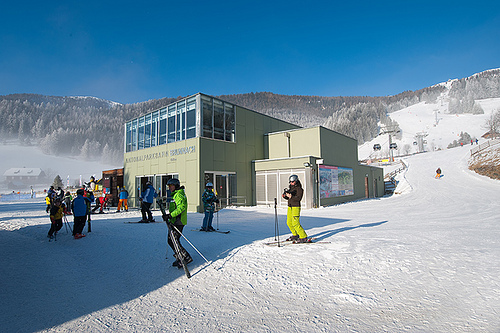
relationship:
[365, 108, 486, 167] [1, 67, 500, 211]
ski lift on top of mountain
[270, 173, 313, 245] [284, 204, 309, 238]
woman wearing ski pants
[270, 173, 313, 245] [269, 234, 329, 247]
woman ready to ski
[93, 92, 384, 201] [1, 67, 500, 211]
ski lodge on top of mountain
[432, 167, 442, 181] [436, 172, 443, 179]
people wearing bright orange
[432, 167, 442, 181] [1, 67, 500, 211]
people coming down mountain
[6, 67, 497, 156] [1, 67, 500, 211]
trees on side of mountain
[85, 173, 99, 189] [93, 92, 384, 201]
blow up penguin next to ski lodge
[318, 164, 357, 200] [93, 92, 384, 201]
map on side of ski lodge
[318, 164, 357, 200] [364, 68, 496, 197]
map for ski hills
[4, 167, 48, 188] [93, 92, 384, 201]
building behind ski lodge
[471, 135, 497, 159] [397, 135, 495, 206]
safety fence along ski trail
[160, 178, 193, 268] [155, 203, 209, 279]
people getting ready to ski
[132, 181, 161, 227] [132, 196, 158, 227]
people getting ready to ski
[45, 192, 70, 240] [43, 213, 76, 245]
people getting ready to ski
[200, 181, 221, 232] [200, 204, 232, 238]
people getting ready to ski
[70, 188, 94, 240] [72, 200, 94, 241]
people getting ready to ski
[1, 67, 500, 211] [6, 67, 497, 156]
mountain covered in trees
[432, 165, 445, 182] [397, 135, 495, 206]
people coming down ski slope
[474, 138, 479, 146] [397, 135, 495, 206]
people coming down ski slope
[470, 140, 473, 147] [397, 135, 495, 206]
people coming down ski slope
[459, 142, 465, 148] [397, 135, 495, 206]
people coming down ski slope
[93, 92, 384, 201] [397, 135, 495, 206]
ski lodge at base of ski slope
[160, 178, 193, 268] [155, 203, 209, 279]
people carrying skis and ski poles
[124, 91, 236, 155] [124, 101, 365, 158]
windows on second floor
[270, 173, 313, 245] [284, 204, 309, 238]
person wearing ski pants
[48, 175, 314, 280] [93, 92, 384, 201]
people near ski lodge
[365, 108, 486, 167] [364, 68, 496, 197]
ski lift in background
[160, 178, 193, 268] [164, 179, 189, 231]
people wearing a jacket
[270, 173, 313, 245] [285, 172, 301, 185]
woman wearing helmet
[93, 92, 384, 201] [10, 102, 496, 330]
ski lodge on top of snow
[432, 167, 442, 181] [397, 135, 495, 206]
people on top of hill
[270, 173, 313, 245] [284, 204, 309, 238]
woman wearing yellow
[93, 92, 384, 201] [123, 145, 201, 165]
ski lodge has writing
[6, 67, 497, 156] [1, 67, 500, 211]
trees on top of mountain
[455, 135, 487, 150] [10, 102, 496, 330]
three people in snow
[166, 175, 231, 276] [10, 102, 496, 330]
two people in snow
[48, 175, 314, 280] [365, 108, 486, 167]
people use ski lift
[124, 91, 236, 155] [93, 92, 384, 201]
windows on side of ski lodge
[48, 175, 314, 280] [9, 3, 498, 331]
skiers in photo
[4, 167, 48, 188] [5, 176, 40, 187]
building made of logs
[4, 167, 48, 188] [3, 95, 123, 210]
building in background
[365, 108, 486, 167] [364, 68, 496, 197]
ski lift on top of slope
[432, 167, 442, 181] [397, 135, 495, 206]
people coming down ski slope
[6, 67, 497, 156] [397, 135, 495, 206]
trees along sides of ski trail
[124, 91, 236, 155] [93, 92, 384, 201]
windows across top of ski lodge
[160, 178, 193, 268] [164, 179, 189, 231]
people wearing jacket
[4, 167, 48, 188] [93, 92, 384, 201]
building next to ski lodge